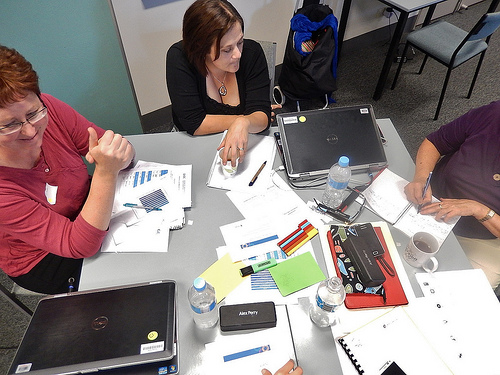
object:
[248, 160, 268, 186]
pen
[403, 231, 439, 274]
cup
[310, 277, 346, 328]
warter bottle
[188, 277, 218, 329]
warter bottle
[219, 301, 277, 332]
eyeglass case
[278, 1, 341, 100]
bookbag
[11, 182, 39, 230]
pink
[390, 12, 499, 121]
chair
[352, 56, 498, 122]
floor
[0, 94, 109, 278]
shirt